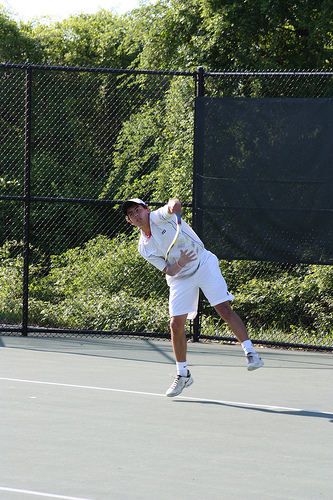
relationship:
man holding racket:
[120, 191, 265, 397] [167, 208, 200, 277]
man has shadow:
[120, 191, 265, 397] [179, 393, 332, 425]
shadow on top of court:
[179, 393, 332, 425] [1, 324, 330, 497]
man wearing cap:
[120, 191, 265, 397] [123, 197, 151, 210]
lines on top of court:
[3, 367, 330, 433] [1, 324, 330, 497]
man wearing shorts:
[120, 191, 265, 397] [159, 255, 226, 313]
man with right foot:
[120, 191, 265, 397] [166, 368, 194, 398]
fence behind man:
[2, 64, 331, 353] [120, 191, 265, 397]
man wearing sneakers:
[120, 191, 265, 397] [171, 353, 266, 402]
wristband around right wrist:
[177, 260, 185, 270] [172, 260, 189, 273]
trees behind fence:
[3, 1, 328, 333] [2, 64, 331, 353]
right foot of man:
[168, 374, 193, 397] [120, 191, 265, 397]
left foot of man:
[246, 349, 265, 372] [120, 191, 265, 397]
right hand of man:
[178, 251, 198, 264] [120, 191, 265, 397]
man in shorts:
[120, 191, 265, 397] [159, 255, 226, 313]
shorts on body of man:
[159, 255, 226, 313] [120, 191, 265, 397]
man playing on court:
[120, 191, 265, 397] [1, 324, 330, 497]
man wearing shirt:
[120, 191, 265, 397] [137, 212, 201, 275]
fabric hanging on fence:
[198, 99, 332, 261] [2, 64, 331, 353]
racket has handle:
[167, 208, 200, 277] [176, 208, 181, 226]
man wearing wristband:
[120, 191, 265, 397] [177, 260, 185, 270]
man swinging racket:
[120, 191, 265, 397] [167, 208, 200, 277]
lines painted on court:
[3, 367, 330, 433] [1, 324, 330, 497]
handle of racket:
[176, 208, 181, 226] [167, 208, 200, 277]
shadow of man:
[179, 393, 332, 425] [120, 191, 265, 397]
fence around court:
[2, 64, 331, 353] [1, 324, 330, 497]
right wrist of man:
[172, 260, 189, 273] [120, 191, 265, 397]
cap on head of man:
[123, 197, 151, 210] [120, 191, 265, 397]